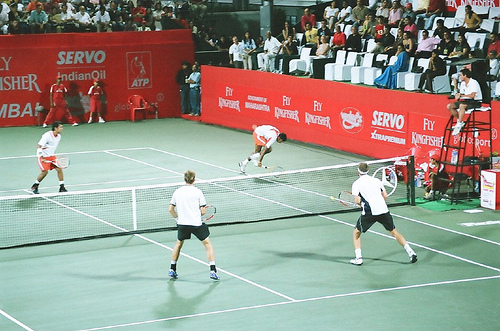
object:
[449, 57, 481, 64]
green canopy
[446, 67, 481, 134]
judge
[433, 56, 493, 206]
chair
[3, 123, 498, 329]
tennis court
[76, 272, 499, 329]
white lines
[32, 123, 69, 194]
man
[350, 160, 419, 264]
man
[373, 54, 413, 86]
blue blanket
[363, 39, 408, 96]
woman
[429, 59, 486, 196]
seat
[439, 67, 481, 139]
referee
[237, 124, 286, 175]
man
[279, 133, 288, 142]
hair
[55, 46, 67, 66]
word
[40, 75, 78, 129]
ball boy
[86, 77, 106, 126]
ball boy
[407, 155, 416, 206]
post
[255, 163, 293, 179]
racket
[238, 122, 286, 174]
player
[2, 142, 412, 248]
tennis net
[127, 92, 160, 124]
red chair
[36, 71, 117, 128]
boys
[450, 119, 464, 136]
shoe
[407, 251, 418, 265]
shoe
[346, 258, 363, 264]
shoe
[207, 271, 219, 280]
shoe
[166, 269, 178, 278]
shoe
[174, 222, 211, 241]
shorts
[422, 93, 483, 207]
high seat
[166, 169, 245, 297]
man